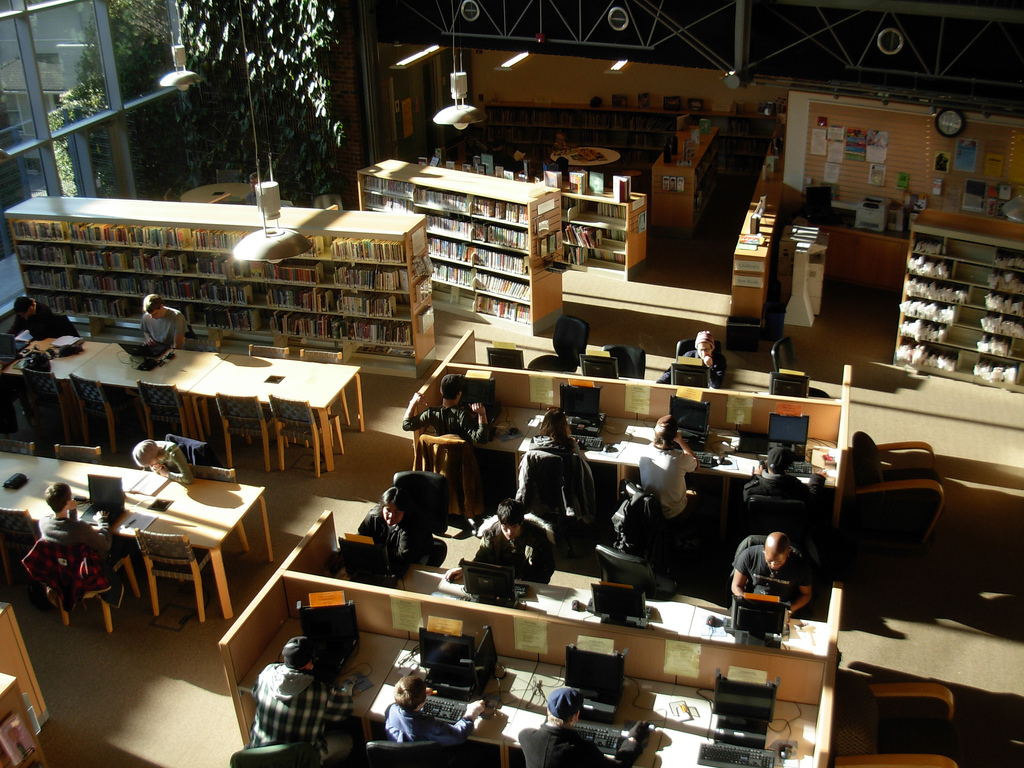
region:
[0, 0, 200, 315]
large glass pane window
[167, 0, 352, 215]
green ivy covered wall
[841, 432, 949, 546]
wooden frame chair with padded seating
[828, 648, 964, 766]
wooden frame chair with padded seating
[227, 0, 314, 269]
silver pendant ceiling fixture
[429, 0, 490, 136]
silver pendant ceiling fixture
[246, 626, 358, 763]
man wearing a plaid shirt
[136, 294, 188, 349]
man in a grey shirt on a computer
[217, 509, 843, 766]
desk with multiple seating areas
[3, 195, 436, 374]
light colored wood bookshelf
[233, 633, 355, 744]
The person in a plaid shirt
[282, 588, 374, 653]
The computer in front the person wearing plaid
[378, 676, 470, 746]
The person in a denim shirt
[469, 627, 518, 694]
The computer monitor not in use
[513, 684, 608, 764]
The man wearing a blue hat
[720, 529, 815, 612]
The person with no hair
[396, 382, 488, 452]
The person that is stretching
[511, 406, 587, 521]
The person with a jacket on the chair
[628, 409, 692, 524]
The person wearing a white shirt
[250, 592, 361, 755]
person in plaid shirt works on black computer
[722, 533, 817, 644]
guy in black tee works on black computer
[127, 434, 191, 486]
person in green top reads on wooden table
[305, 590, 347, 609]
yellow sign above black computer monitor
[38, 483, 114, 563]
guy with brown hair works on black laptop computer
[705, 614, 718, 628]
black computer mouse on wooden huge wooden desk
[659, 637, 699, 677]
white sign taped to big wooden desk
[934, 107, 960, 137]
black clock with white face on far back wall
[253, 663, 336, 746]
The man is wearing a plaid jacket.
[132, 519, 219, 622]
This is a empty seat by the table.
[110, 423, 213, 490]
A person is sitting at the table reading.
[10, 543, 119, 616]
A red jacket is hung over the back of the chair.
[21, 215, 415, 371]
A bookcase with many books.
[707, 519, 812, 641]
A man at the computer on the desk.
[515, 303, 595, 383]
A large black chair.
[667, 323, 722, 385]
A woman looking at the computer screen.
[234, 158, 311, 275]
A light hanging from the ceiling.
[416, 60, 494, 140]
A light hanging from the ceiling.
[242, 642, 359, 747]
a person is sitting down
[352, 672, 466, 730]
a person is sitting down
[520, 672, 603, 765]
a person is sitting down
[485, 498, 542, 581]
a person is sitting down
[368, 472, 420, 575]
a person is sitting down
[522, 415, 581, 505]
a person is sitting down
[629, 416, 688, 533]
a person is sitting down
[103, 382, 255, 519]
The person is sitting at the desk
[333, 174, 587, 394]
The books are on the shelf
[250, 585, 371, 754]
The person is using the computer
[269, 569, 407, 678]
An orange sign behind the computer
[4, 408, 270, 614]
A shadow is on the table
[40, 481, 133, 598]
Man using a laptop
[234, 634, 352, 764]
Man using a computer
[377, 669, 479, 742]
Man using a computer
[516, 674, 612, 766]
Man wearing a blue hat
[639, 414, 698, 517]
Man wearing a beige shirt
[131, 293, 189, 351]
Man wearing a gray shirt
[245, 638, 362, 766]
Man wearing a plaid jacket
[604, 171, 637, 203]
Book standing on the bookshelf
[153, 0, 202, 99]
Light hanging above the table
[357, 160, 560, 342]
a book shelf in a library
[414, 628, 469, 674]
a computer monitor